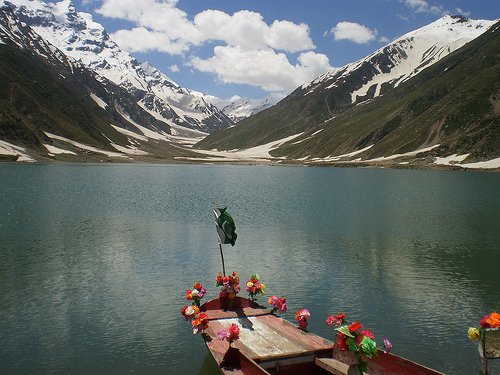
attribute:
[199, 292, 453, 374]
boat — wooden, red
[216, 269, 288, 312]
flowers — colored, green, yellow, red, decorated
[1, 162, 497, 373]
lake — coloured, short, large, painted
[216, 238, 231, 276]
pole — fish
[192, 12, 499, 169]
mountain — snowy, rocky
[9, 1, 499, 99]
sky — blue